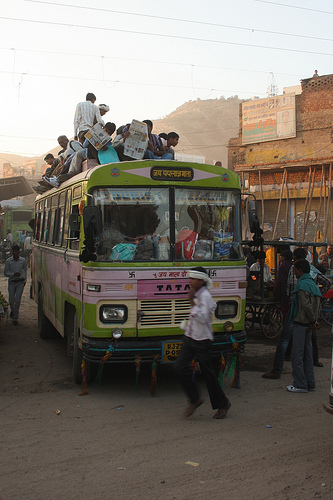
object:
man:
[174, 267, 231, 420]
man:
[73, 91, 105, 159]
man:
[42, 134, 84, 183]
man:
[4, 243, 27, 326]